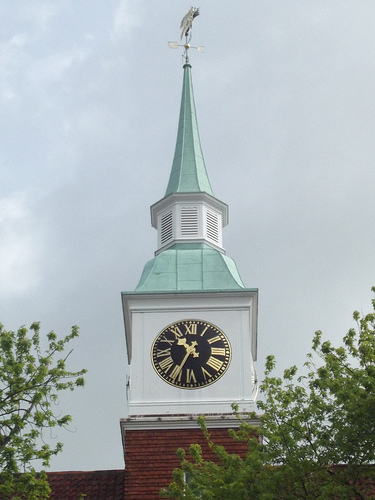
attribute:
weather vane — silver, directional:
[170, 3, 202, 64]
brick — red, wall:
[0, 429, 373, 498]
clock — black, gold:
[153, 320, 229, 387]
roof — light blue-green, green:
[117, 243, 257, 301]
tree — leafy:
[147, 291, 373, 499]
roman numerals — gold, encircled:
[180, 319, 197, 338]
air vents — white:
[157, 206, 220, 246]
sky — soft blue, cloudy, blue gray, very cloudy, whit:
[1, 0, 372, 473]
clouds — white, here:
[0, 2, 373, 470]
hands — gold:
[169, 337, 198, 381]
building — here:
[3, 432, 372, 499]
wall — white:
[120, 302, 258, 418]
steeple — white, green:
[120, 300, 258, 416]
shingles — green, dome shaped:
[131, 243, 247, 292]